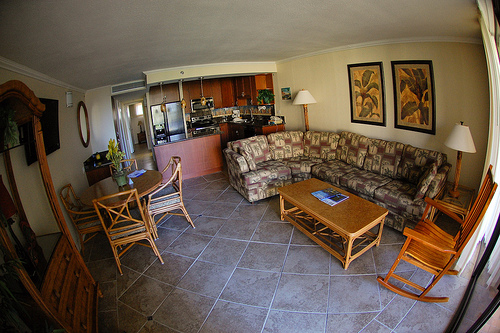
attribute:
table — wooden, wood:
[252, 161, 406, 253]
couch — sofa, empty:
[213, 115, 474, 212]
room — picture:
[4, 31, 470, 325]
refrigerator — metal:
[145, 91, 207, 160]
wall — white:
[0, 89, 122, 268]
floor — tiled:
[188, 246, 275, 311]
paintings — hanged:
[330, 45, 461, 154]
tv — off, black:
[11, 95, 74, 166]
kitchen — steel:
[151, 88, 187, 148]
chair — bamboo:
[95, 174, 199, 286]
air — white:
[52, 72, 99, 116]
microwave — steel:
[184, 89, 226, 123]